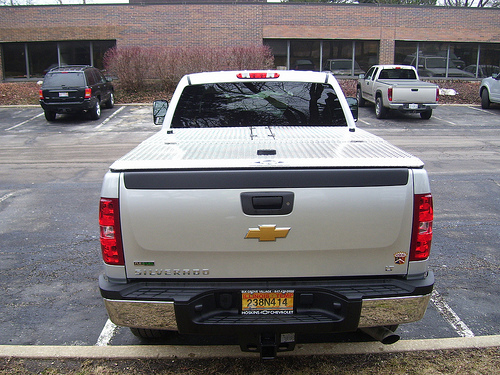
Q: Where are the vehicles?
A: Parking lot.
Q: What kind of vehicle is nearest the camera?
A: Truck.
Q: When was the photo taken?
A: Daytime.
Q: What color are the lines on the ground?
A: White.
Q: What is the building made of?
A: Bricks.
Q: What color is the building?
A: Red.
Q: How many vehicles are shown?
A: Four.